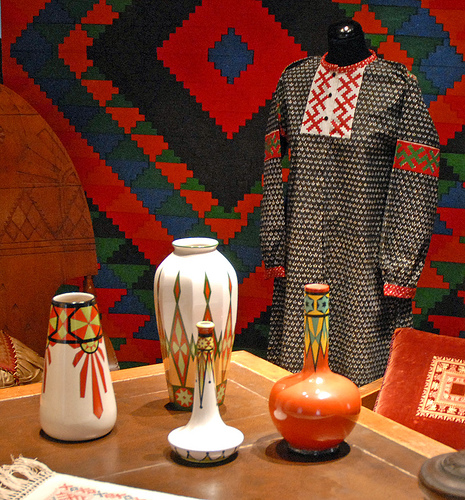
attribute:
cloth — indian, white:
[0, 456, 199, 499]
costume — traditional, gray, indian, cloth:
[260, 49, 439, 387]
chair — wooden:
[0, 85, 106, 359]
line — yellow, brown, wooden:
[0, 345, 462, 498]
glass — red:
[267, 282, 361, 452]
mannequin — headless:
[318, 21, 373, 68]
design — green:
[265, 130, 440, 178]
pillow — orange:
[372, 325, 463, 447]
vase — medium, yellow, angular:
[36, 288, 119, 445]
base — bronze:
[287, 438, 341, 454]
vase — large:
[154, 234, 240, 409]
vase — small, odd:
[168, 322, 245, 467]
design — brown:
[0, 341, 7, 364]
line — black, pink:
[305, 66, 360, 135]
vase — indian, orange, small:
[269, 282, 366, 457]